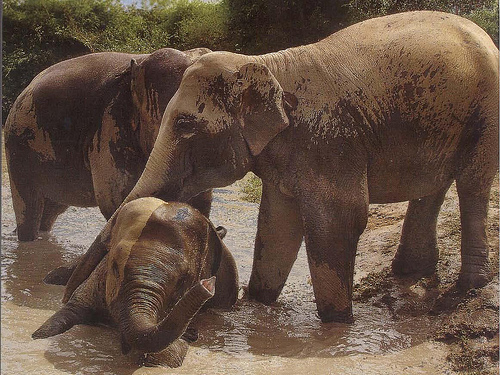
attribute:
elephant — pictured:
[3, 49, 224, 250]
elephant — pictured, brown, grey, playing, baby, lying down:
[33, 197, 240, 368]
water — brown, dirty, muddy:
[0, 121, 457, 374]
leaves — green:
[0, 1, 499, 127]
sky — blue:
[93, 0, 225, 13]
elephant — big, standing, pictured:
[62, 9, 500, 324]